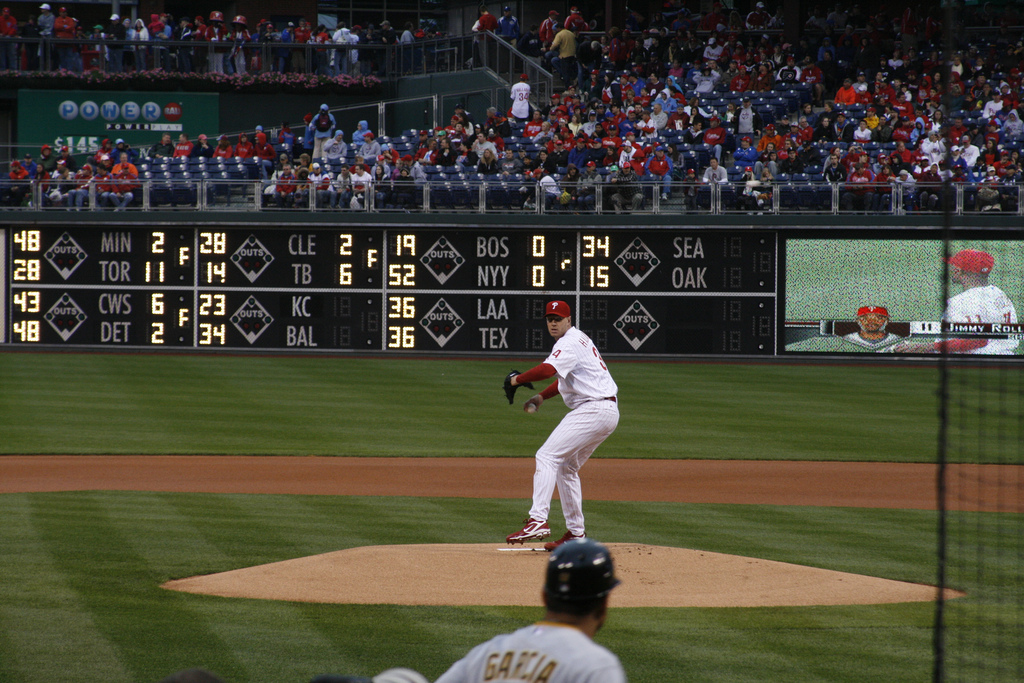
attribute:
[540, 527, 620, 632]
helmet — black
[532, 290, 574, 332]
hat — red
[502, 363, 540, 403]
glove — black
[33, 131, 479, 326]
wall — black